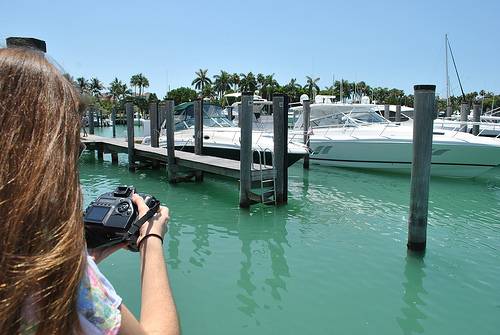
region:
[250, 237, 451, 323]
Barely rippling, green-blue water.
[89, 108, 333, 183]
Grey dock with high posts.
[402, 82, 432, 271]
Single post, submerged in water.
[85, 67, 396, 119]
Tall palm trees, lining coastline.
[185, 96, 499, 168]
White boats docked in harbor.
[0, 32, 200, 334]
Back of brown-haired woman holding camera.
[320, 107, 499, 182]
Bow of sleek boat with stripe.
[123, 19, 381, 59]
Pale, blue summery sky, without clouds.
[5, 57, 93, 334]
Thick, long, shoulder-length brown hair on woman.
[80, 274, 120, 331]
Pink, blue and white short sleeve on woman.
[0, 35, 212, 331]
a photo of a girl taking a photo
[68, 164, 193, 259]
an antique camera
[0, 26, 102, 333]
lovely shining long hair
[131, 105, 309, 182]
a boat in its dock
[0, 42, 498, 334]
murky green water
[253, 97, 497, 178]
a pretty nice boat with built in shade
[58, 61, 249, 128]
palm trees in the distance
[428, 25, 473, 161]
the mast of a sailboat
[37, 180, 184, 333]
the girl's right arm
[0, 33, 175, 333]
hair in a slight wind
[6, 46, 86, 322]
sun shines on woman brown hair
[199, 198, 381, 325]
water in a harbor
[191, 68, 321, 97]
palm trees in the distance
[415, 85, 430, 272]
pillars in the water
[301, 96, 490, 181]
sleek white speed boat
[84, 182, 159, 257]
woman is holding a digital camera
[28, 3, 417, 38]
blue sky has no clouds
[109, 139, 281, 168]
wooden pier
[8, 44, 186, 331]
woman is photographing the boats in the harbor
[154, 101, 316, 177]
boat docked alongside the harbor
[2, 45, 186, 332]
a girl holds a camera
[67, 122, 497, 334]
the water is turquiose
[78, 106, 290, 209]
a wooden dock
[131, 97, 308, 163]
a white boat at the dock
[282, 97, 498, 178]
a white boat in the water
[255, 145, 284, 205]
a metal ladder attached to the dock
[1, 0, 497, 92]
the sky is very blue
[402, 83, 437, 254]
a wooden post sticking out of the water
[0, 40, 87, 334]
the girl has long brown hair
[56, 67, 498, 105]
palm trees behind the boats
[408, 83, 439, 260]
this is a post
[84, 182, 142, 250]
this is a camera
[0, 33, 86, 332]
this is the photographers hair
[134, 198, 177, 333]
photographer's arm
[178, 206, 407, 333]
this is water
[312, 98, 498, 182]
this is a boat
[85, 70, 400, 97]
these are trees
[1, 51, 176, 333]
she is taking a photo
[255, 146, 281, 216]
these are stairs from the water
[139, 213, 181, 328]
the photographer is white in color